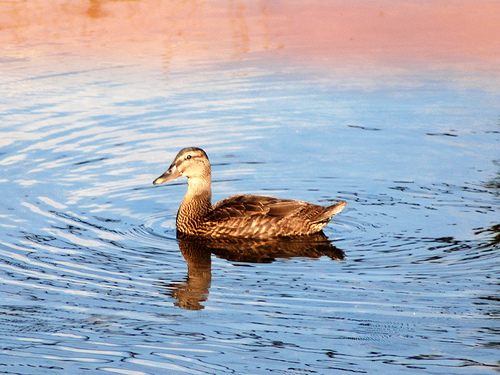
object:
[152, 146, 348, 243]
duck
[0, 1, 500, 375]
water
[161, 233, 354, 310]
reflection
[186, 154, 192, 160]
eye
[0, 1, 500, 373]
scene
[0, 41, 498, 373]
body of water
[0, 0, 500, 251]
daylight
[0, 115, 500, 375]
whorl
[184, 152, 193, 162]
rim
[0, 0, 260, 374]
left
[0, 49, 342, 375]
sunlight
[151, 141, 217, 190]
head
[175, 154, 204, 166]
stripe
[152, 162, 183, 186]
beak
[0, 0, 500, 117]
odd hue effect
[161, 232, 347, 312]
distortion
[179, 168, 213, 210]
neck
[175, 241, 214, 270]
perfect reflection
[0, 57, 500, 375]
ripple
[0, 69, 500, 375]
pond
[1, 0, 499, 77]
pink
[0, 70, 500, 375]
blue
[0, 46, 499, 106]
haze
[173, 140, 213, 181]
highlights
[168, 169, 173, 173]
nostril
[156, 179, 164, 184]
yellow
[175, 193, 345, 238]
feathers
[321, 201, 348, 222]
tail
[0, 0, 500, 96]
orange marks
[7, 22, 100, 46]
orange marks